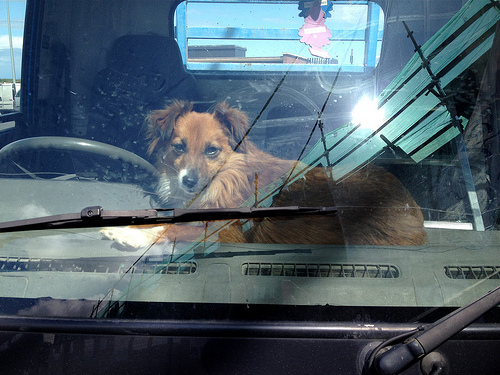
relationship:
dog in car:
[104, 100, 429, 252] [0, 1, 496, 372]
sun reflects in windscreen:
[343, 88, 388, 136] [1, 2, 495, 322]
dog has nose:
[104, 100, 429, 252] [183, 172, 197, 186]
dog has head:
[104, 100, 429, 252] [165, 113, 232, 196]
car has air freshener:
[0, 1, 496, 372] [300, 7, 332, 51]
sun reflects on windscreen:
[343, 88, 388, 136] [1, 2, 495, 322]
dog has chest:
[104, 100, 429, 252] [156, 170, 181, 213]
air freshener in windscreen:
[300, 7, 332, 51] [1, 2, 495, 322]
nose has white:
[183, 172, 197, 186] [177, 167, 186, 192]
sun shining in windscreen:
[343, 88, 388, 136] [1, 2, 495, 322]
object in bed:
[186, 43, 309, 63] [175, 6, 380, 79]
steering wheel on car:
[3, 136, 163, 193] [0, 1, 496, 372]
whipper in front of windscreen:
[363, 287, 494, 375] [1, 2, 495, 322]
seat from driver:
[87, 32, 198, 145] [86, 34, 203, 159]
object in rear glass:
[186, 43, 309, 63] [171, 1, 386, 73]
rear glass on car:
[171, 1, 386, 73] [0, 1, 496, 372]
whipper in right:
[0, 203, 338, 230] [3, 141, 340, 311]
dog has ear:
[104, 100, 429, 252] [214, 98, 249, 155]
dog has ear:
[104, 100, 429, 252] [142, 97, 192, 156]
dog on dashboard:
[104, 100, 429, 252] [1, 175, 499, 304]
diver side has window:
[26, 37, 197, 176] [0, 3, 38, 119]